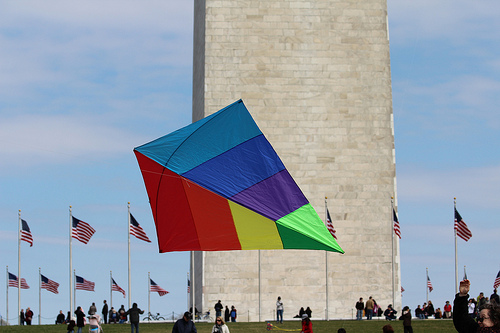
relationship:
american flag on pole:
[455, 207, 474, 244] [453, 196, 459, 308]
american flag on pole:
[441, 200, 480, 245] [451, 235, 461, 316]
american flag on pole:
[384, 200, 405, 235] [391, 234, 399, 300]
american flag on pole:
[321, 199, 338, 239] [323, 240, 330, 315]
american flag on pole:
[120, 209, 156, 248] [123, 239, 133, 309]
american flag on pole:
[65, 210, 98, 245] [66, 244, 76, 314]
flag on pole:
[106, 270, 126, 301] [108, 292, 112, 322]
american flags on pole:
[75, 275, 95, 292] [71, 269, 77, 326]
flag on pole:
[423, 270, 437, 292] [378, 196, 490, 219]